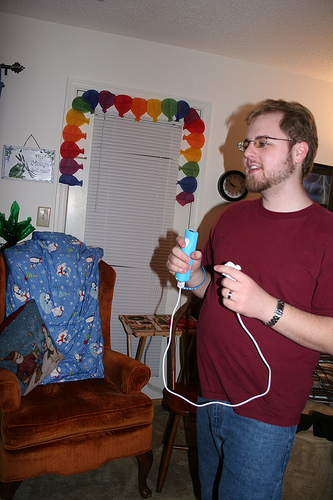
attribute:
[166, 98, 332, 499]
man — playing video game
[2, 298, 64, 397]
pillow — christmas themed, for christmas, holiday themed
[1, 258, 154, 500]
chair — orange, light brown, cushioned, brown, red, stuffed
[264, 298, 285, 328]
watch — silver, metal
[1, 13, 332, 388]
wall — white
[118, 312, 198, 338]
tray — wooden, in background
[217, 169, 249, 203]
clock — round, circular, black, black framed, white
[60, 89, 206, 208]
balloon decoration — colorful, paper, multi colored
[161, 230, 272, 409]
wii remote control — present, blue, white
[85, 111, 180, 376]
blinds — white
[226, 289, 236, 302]
ring — metal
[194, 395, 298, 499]
jeans — dark blue, blue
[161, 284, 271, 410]
wire — white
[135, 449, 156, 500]
leg — wooden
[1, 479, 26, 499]
leg — wooden